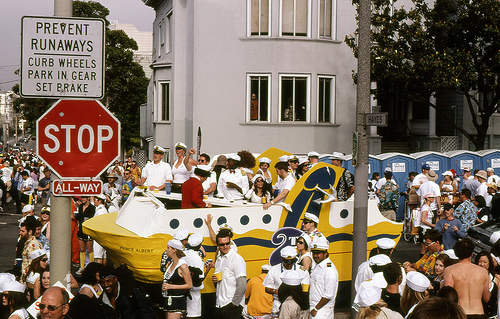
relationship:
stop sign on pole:
[35, 99, 120, 179] [47, 4, 91, 249]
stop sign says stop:
[35, 99, 120, 179] [36, 117, 113, 158]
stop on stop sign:
[36, 117, 113, 158] [35, 99, 120, 179]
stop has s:
[36, 117, 113, 158] [46, 126, 63, 157]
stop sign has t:
[35, 99, 120, 179] [62, 118, 79, 157]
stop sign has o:
[35, 99, 120, 179] [72, 122, 94, 157]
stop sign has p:
[35, 99, 120, 179] [93, 118, 108, 154]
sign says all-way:
[49, 172, 103, 201] [49, 180, 105, 206]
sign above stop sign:
[22, 13, 109, 102] [32, 93, 129, 199]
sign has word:
[22, 13, 109, 102] [29, 20, 83, 91]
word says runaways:
[29, 20, 83, 91] [32, 35, 96, 52]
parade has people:
[141, 178, 460, 252] [148, 229, 494, 312]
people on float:
[252, 174, 369, 210] [100, 169, 418, 277]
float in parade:
[100, 169, 418, 277] [141, 178, 460, 252]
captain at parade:
[147, 145, 178, 214] [141, 178, 460, 252]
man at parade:
[445, 240, 493, 314] [141, 178, 460, 252]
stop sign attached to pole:
[32, 93, 129, 199] [47, 4, 91, 249]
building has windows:
[147, 5, 399, 163] [240, 71, 341, 124]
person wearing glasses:
[205, 235, 243, 316] [220, 242, 235, 250]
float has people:
[100, 169, 418, 277] [252, 174, 369, 210]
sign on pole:
[22, 13, 109, 102] [47, 4, 91, 249]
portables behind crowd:
[362, 148, 498, 177] [339, 178, 499, 294]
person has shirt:
[309, 242, 341, 314] [311, 266, 339, 306]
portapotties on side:
[362, 148, 498, 177] [324, 122, 494, 141]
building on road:
[147, 5, 399, 163] [118, 157, 427, 163]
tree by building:
[376, 10, 493, 129] [147, 5, 399, 163]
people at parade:
[148, 229, 494, 312] [141, 178, 460, 252]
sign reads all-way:
[49, 172, 103, 201] [49, 180, 105, 206]